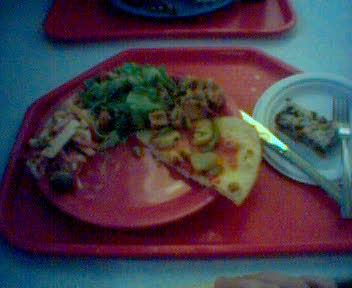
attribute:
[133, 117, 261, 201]
pizza — various, toppings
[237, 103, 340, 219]
knife — silver, reflective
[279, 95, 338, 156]
dessert — rectangular, piece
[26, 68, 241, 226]
plate — red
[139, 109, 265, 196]
food items — group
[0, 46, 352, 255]
tray — red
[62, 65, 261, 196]
pizza — one, piece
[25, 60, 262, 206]
pizza — topped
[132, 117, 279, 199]
food — piece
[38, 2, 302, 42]
lunch tray — edge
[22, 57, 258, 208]
food — part